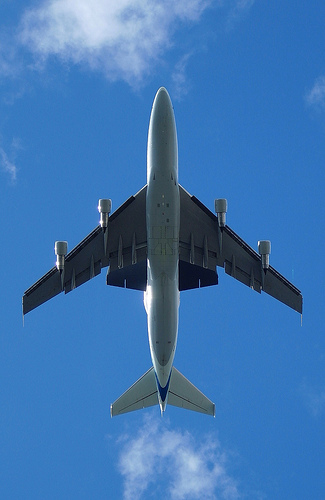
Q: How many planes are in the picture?
A: One.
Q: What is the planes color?
A: White.